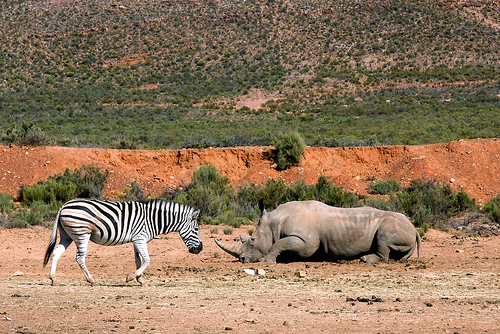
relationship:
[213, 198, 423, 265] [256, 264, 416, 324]
rhinocerous on dirt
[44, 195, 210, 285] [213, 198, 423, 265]
zebra beside rhinocerous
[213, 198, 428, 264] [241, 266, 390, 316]
rhinocerous on dirt